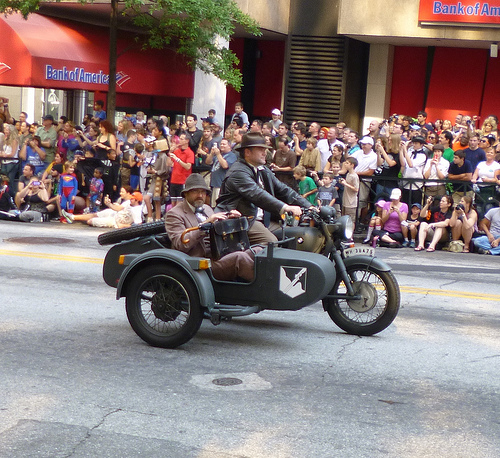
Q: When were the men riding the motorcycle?
A: Daytime.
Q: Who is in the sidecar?
A: A man.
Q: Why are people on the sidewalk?
A: To watch a parade.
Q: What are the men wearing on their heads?
A: Hats.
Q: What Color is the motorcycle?
A: Gray.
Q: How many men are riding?
A: Two.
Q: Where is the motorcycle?
A: On the street.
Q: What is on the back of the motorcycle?
A: Spare tire.